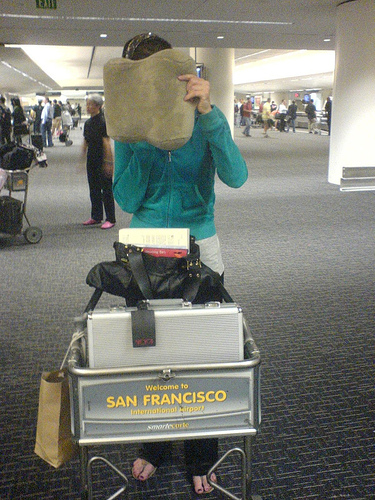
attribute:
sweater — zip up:
[114, 107, 249, 236]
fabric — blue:
[111, 102, 251, 237]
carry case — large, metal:
[88, 302, 242, 369]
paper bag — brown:
[34, 368, 79, 468]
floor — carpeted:
[293, 179, 324, 211]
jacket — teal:
[95, 99, 258, 243]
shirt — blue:
[76, 97, 232, 234]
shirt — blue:
[106, 102, 247, 240]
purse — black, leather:
[84, 233, 233, 306]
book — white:
[114, 226, 193, 259]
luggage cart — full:
[0, 139, 49, 246]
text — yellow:
[105, 379, 234, 430]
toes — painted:
[130, 462, 143, 478]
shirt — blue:
[104, 93, 249, 245]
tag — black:
[129, 302, 157, 348]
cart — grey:
[69, 308, 261, 497]